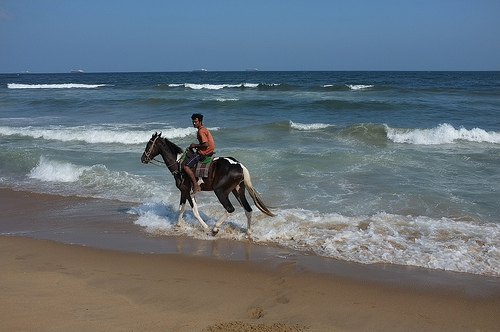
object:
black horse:
[139, 131, 277, 237]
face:
[141, 141, 160, 164]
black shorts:
[185, 152, 200, 167]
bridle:
[144, 136, 158, 161]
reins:
[149, 158, 166, 167]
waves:
[381, 121, 499, 144]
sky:
[1, 0, 497, 71]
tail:
[238, 163, 274, 217]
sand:
[29, 267, 146, 310]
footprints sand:
[200, 320, 308, 331]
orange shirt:
[197, 126, 216, 155]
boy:
[183, 113, 215, 194]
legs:
[212, 188, 235, 235]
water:
[0, 72, 497, 275]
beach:
[0, 211, 442, 329]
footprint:
[276, 295, 291, 304]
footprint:
[245, 304, 265, 321]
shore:
[10, 176, 499, 327]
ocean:
[0, 72, 497, 271]